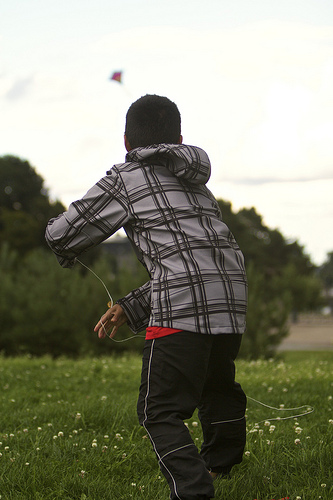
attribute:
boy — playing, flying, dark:
[108, 90, 273, 466]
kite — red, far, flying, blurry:
[102, 66, 135, 90]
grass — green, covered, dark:
[35, 375, 86, 441]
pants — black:
[147, 340, 229, 431]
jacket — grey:
[141, 170, 224, 306]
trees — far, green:
[5, 214, 40, 287]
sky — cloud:
[221, 16, 264, 42]